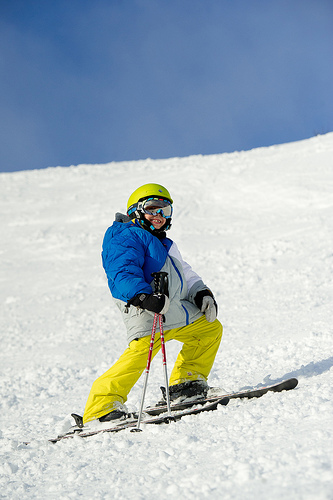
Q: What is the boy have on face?
A: Snow glasses.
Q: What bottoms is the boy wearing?
A: Yellow.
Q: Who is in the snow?
A: Young man.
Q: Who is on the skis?
A: Young man.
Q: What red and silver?
A: Ski poles.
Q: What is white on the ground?
A: Snow.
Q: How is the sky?
A: Clear blue.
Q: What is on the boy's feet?
A: Skis.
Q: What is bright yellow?
A: Boy's pants.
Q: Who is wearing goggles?
A: The skier.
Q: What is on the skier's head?
A: Helmet.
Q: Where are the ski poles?
A: Right hand.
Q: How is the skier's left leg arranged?
A: Bent.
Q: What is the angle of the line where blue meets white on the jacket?
A: Diagonal.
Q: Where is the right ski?
A: Below the left ski.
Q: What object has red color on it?
A: Ski poles.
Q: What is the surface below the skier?
A: Snow.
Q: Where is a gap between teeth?
A: Skier's mouth.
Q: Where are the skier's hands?
A: In gloves.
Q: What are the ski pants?
A: Yellow.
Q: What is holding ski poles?
A: The young boy.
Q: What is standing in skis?
A: The young boy.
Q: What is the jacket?
A: Blue and gray.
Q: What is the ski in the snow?
A: Long.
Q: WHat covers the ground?
A: Snow.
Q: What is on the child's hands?
A: Gloves.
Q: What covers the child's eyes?
A: Goggles.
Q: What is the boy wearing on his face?
A: Goggles.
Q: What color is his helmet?
A: Yellow.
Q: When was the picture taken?
A: Daytime outside.